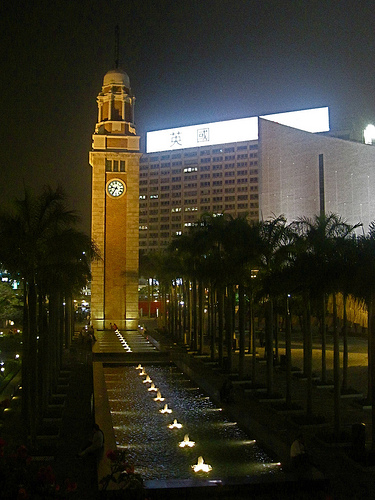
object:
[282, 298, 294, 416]
trunks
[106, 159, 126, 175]
windows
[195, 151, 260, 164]
window row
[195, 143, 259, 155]
window row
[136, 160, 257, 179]
window row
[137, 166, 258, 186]
window row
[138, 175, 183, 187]
window row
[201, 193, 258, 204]
window row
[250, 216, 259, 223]
window row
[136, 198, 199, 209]
window row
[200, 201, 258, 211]
window row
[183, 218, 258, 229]
window row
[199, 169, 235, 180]
window row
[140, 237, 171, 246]
window row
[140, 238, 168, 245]
window row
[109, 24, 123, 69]
pole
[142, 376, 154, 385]
candle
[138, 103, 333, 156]
billboard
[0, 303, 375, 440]
ground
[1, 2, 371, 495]
hong kong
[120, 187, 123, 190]
numbers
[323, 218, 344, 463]
trees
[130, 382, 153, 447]
water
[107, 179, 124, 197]
clock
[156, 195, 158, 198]
window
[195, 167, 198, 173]
window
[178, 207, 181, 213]
window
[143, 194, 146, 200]
window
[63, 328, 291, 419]
floor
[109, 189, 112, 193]
markings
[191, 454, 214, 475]
candle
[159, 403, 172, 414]
candle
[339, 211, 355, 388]
trees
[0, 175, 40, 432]
trees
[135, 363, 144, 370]
light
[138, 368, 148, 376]
light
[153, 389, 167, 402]
light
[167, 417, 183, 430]
light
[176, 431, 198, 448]
light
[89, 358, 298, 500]
pool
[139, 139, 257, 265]
hotel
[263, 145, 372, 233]
wall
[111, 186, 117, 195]
hand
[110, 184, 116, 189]
hand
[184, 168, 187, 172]
lights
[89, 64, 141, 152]
dome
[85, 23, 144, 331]
building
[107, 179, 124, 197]
face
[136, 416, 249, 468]
water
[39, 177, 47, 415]
tree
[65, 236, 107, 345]
tree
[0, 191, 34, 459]
tree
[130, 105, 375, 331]
building